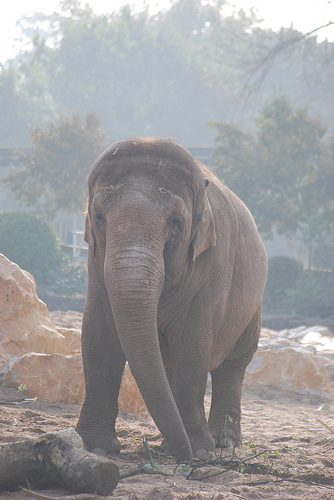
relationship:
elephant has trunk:
[74, 137, 267, 464] [104, 197, 193, 462]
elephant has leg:
[74, 137, 267, 464] [74, 239, 125, 453]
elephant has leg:
[74, 137, 267, 464] [165, 281, 214, 461]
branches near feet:
[136, 426, 272, 480] [68, 396, 247, 457]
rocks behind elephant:
[2, 255, 331, 400] [74, 137, 267, 464]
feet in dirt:
[64, 424, 251, 458] [1, 394, 333, 492]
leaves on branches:
[224, 434, 282, 454] [191, 443, 278, 483]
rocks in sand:
[259, 327, 333, 397] [245, 393, 332, 478]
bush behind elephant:
[295, 273, 333, 321] [74, 137, 267, 464]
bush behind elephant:
[260, 253, 309, 315] [74, 137, 267, 464]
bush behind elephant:
[0, 215, 62, 285] [74, 137, 267, 464]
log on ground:
[0, 433, 117, 496] [9, 384, 332, 498]